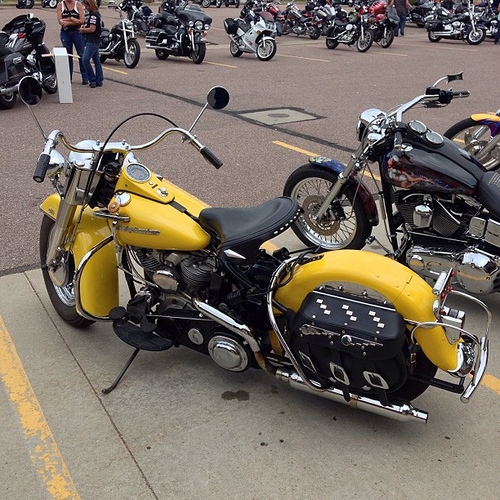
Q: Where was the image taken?
A: It was taken at the parking lot.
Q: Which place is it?
A: It is a parking lot.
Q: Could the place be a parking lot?
A: Yes, it is a parking lot.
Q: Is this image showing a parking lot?
A: Yes, it is showing a parking lot.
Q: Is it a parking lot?
A: Yes, it is a parking lot.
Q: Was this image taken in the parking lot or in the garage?
A: It was taken at the parking lot.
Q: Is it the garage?
A: No, it is the parking lot.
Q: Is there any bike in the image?
A: Yes, there are bikes.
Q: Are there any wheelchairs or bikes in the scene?
A: Yes, there are bikes.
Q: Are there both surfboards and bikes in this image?
A: No, there are bikes but no surfboards.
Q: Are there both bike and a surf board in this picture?
A: No, there are bikes but no surfboards.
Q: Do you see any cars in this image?
A: No, there are no cars.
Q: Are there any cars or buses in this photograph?
A: No, there are no cars or buses.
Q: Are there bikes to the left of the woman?
A: Yes, there are bikes to the left of the woman.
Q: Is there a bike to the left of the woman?
A: Yes, there are bikes to the left of the woman.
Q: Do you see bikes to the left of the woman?
A: Yes, there are bikes to the left of the woman.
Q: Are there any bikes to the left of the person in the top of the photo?
A: Yes, there are bikes to the left of the woman.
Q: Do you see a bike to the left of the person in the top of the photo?
A: Yes, there are bikes to the left of the woman.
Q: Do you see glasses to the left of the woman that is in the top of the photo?
A: No, there are bikes to the left of the woman.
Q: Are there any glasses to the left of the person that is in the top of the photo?
A: No, there are bikes to the left of the woman.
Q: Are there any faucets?
A: No, there are no faucets.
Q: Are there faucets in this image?
A: No, there are no faucets.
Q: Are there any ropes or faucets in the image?
A: No, there are no faucets or ropes.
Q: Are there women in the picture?
A: Yes, there is a woman.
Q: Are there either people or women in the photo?
A: Yes, there is a woman.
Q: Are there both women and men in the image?
A: No, there is a woman but no men.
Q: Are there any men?
A: No, there are no men.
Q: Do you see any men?
A: No, there are no men.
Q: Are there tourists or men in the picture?
A: No, there are no men or tourists.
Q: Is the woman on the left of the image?
A: Yes, the woman is on the left of the image.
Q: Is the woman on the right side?
A: No, the woman is on the left of the image.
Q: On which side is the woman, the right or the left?
A: The woman is on the left of the image.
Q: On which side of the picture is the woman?
A: The woman is on the left of the image.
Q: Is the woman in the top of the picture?
A: Yes, the woman is in the top of the image.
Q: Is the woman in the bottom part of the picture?
A: No, the woman is in the top of the image.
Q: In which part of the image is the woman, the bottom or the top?
A: The woman is in the top of the image.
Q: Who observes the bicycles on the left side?
A: The woman observes the bikes.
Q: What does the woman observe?
A: The woman observes the bicycles.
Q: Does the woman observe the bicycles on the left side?
A: Yes, the woman observes the bikes.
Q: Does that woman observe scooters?
A: No, the woman observes the bikes.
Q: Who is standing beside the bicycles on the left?
A: The woman is standing beside the bikes.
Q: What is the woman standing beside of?
A: The woman is standing beside the bicycles.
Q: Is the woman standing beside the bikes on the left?
A: Yes, the woman is standing beside the bicycles.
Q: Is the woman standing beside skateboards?
A: No, the woman is standing beside the bicycles.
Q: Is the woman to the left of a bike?
A: Yes, the woman is to the left of a bike.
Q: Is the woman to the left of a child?
A: No, the woman is to the left of a bike.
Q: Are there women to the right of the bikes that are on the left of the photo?
A: Yes, there is a woman to the right of the bicycles.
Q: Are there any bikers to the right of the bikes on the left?
A: No, there is a woman to the right of the bicycles.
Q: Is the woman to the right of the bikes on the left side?
A: Yes, the woman is to the right of the bicycles.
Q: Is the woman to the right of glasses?
A: No, the woman is to the right of the bicycles.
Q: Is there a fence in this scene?
A: No, there are no fences.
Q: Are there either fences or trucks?
A: No, there are no fences or trucks.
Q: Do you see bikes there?
A: Yes, there is a bike.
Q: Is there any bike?
A: Yes, there is a bike.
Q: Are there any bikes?
A: Yes, there is a bike.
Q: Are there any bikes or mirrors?
A: Yes, there is a bike.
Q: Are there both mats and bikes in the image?
A: No, there is a bike but no mats.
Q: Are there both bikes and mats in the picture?
A: No, there is a bike but no mats.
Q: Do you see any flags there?
A: No, there are no flags.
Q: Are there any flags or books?
A: No, there are no flags or books.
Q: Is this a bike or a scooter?
A: This is a bike.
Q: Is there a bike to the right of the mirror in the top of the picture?
A: Yes, there is a bike to the right of the mirror.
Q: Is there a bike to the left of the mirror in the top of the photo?
A: No, the bike is to the right of the mirror.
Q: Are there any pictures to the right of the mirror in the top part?
A: No, there is a bike to the right of the mirror.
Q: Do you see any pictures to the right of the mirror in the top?
A: No, there is a bike to the right of the mirror.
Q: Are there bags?
A: Yes, there is a bag.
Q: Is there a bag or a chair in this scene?
A: Yes, there is a bag.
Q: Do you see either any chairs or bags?
A: Yes, there is a bag.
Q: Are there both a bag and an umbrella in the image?
A: No, there is a bag but no umbrellas.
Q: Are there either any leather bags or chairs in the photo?
A: Yes, there is a leather bag.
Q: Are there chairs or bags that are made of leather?
A: Yes, the bag is made of leather.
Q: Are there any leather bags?
A: Yes, there is a bag that is made of leather.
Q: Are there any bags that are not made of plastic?
A: Yes, there is a bag that is made of leather.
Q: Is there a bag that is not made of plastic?
A: Yes, there is a bag that is made of leather.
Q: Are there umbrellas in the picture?
A: No, there are no umbrellas.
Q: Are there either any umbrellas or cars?
A: No, there are no umbrellas or cars.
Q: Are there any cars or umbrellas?
A: No, there are no umbrellas or cars.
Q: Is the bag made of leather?
A: Yes, the bag is made of leather.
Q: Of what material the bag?
A: The bag is made of leather.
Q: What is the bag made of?
A: The bag is made of leather.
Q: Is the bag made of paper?
A: No, the bag is made of leather.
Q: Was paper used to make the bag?
A: No, the bag is made of leather.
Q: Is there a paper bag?
A: No, there is a bag but it is made of leather.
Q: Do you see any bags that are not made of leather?
A: No, there is a bag but it is made of leather.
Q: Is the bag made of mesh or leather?
A: The bag is made of leather.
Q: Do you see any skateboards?
A: No, there are no skateboards.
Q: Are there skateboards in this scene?
A: No, there are no skateboards.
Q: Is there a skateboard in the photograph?
A: No, there are no skateboards.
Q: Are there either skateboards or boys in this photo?
A: No, there are no skateboards or boys.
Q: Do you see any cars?
A: No, there are no cars.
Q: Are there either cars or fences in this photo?
A: No, there are no cars or fences.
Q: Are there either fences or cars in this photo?
A: No, there are no cars or fences.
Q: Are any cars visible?
A: No, there are no cars.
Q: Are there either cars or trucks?
A: No, there are no cars or trucks.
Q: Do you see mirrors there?
A: Yes, there is a mirror.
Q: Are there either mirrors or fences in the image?
A: Yes, there is a mirror.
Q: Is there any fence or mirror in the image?
A: Yes, there is a mirror.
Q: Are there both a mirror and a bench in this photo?
A: No, there is a mirror but no benches.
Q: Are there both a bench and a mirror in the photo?
A: No, there is a mirror but no benches.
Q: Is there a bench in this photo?
A: No, there are no benches.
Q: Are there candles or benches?
A: No, there are no benches or candles.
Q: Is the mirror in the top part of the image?
A: Yes, the mirror is in the top of the image.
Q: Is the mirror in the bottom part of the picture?
A: No, the mirror is in the top of the image.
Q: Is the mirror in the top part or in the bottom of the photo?
A: The mirror is in the top of the image.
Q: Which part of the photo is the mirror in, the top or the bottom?
A: The mirror is in the top of the image.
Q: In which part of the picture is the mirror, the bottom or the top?
A: The mirror is in the top of the image.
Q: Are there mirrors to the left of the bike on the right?
A: Yes, there is a mirror to the left of the bike.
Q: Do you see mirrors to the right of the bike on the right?
A: No, the mirror is to the left of the bike.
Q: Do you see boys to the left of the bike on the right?
A: No, there is a mirror to the left of the bike.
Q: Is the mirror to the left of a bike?
A: Yes, the mirror is to the left of a bike.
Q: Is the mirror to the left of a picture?
A: No, the mirror is to the left of a bike.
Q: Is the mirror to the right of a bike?
A: No, the mirror is to the left of a bike.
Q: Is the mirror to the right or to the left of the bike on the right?
A: The mirror is to the left of the bike.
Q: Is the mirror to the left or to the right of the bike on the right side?
A: The mirror is to the left of the bike.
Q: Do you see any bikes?
A: Yes, there is a bike.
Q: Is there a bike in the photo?
A: Yes, there is a bike.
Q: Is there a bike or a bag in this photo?
A: Yes, there is a bike.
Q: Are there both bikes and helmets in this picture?
A: No, there is a bike but no helmets.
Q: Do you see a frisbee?
A: No, there are no frisbees.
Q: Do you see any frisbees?
A: No, there are no frisbees.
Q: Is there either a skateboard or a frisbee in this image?
A: No, there are no frisbees or skateboards.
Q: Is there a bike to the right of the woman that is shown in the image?
A: Yes, there is a bike to the right of the woman.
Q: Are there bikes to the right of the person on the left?
A: Yes, there is a bike to the right of the woman.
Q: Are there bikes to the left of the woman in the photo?
A: No, the bike is to the right of the woman.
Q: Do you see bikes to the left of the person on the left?
A: No, the bike is to the right of the woman.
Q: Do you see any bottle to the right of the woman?
A: No, there is a bike to the right of the woman.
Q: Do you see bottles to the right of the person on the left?
A: No, there is a bike to the right of the woman.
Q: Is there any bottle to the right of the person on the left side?
A: No, there is a bike to the right of the woman.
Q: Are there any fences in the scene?
A: No, there are no fences.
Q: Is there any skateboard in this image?
A: No, there are no skateboards.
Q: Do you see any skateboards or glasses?
A: No, there are no skateboards or glasses.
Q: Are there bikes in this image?
A: Yes, there is a bike.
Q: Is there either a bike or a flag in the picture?
A: Yes, there is a bike.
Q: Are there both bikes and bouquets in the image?
A: No, there is a bike but no bouquets.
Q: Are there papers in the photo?
A: No, there are no papers.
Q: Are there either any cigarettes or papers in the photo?
A: No, there are no papers or cigarettes.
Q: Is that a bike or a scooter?
A: That is a bike.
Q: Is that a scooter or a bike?
A: That is a bike.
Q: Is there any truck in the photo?
A: No, there are no trucks.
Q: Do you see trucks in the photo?
A: No, there are no trucks.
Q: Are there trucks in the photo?
A: No, there are no trucks.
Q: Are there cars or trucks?
A: No, there are no trucks or cars.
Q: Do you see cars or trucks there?
A: No, there are no trucks or cars.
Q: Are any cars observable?
A: No, there are no cars.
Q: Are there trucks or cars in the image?
A: No, there are no cars or trucks.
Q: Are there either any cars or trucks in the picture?
A: No, there are no cars or trucks.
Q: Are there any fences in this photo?
A: No, there are no fences.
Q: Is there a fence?
A: No, there are no fences.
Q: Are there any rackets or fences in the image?
A: No, there are no fences or rackets.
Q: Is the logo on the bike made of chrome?
A: Yes, the logo is made of chrome.